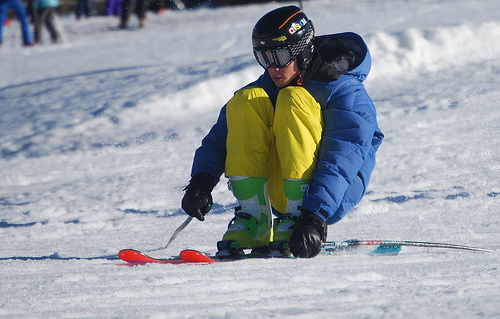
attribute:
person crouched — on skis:
[173, 5, 387, 264]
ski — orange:
[118, 245, 178, 267]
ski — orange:
[176, 242, 223, 262]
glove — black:
[284, 203, 328, 259]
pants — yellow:
[221, 82, 324, 179]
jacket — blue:
[185, 27, 386, 231]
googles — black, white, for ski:
[240, 42, 308, 70]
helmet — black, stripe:
[231, 13, 321, 60]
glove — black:
[167, 179, 224, 213]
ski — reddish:
[95, 242, 235, 287]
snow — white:
[89, 72, 155, 123]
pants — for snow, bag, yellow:
[221, 97, 309, 217]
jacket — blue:
[210, 86, 364, 195]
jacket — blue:
[190, 63, 338, 213]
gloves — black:
[290, 200, 329, 255]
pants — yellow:
[216, 94, 330, 243]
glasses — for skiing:
[234, 29, 319, 79]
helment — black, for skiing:
[252, 22, 317, 72]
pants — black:
[28, 9, 63, 49]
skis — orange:
[90, 241, 424, 281]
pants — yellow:
[207, 79, 318, 247]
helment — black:
[250, 6, 321, 74]